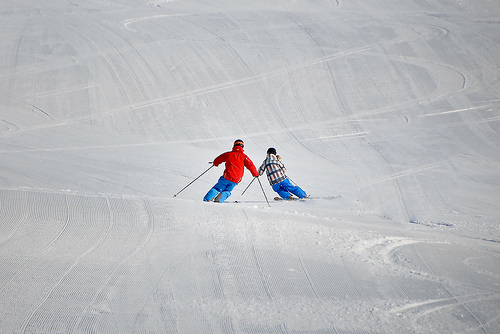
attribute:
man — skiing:
[202, 137, 258, 203]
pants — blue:
[204, 171, 238, 203]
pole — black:
[175, 161, 216, 197]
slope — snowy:
[0, 1, 499, 333]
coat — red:
[211, 147, 258, 182]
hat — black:
[265, 146, 278, 154]